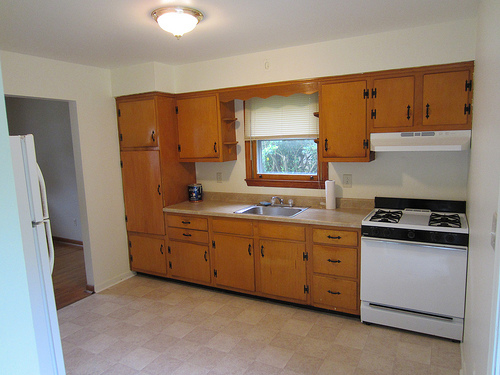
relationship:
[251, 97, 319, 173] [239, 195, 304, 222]
window above sink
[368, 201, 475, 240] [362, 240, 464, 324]
stove top with oven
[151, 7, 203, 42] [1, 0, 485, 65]
dome light attached to ceiling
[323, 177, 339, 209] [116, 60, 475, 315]
paper on cabinet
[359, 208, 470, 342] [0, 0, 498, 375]
oven in kitchen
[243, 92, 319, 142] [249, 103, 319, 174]
blinds on window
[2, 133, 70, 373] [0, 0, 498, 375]
fridge in kitchen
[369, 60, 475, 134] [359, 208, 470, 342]
cabinet above oven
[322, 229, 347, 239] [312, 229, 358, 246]
knob on drawer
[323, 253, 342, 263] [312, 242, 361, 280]
knob on drawer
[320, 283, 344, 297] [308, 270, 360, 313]
knob on drawer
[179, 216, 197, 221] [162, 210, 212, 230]
knob on drawer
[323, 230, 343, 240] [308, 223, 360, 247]
knob on drawer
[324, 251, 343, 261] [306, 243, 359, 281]
knob on drawer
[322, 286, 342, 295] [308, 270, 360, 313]
knob on drawer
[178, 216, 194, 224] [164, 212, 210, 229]
knob on drawer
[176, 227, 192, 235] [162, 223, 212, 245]
knob on drawer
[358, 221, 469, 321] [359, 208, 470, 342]
oven on oven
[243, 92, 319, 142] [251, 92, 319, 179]
blinds on window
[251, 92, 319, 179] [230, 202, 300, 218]
window above sink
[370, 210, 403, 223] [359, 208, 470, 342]
burner on oven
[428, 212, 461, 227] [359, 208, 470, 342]
burner on oven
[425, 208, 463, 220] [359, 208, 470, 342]
burner on oven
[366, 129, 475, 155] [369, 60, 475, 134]
exhaust under cabinet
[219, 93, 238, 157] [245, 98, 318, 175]
shelves beside window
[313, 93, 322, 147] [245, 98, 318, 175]
shelves beside window